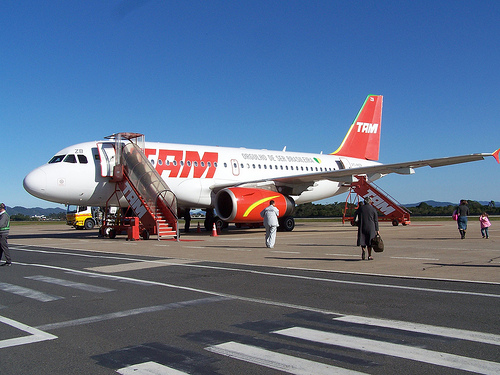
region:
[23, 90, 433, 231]
orange and white plane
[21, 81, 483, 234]
white and orange plane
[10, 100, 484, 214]
airplane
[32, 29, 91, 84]
white clouds in blue sky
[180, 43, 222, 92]
white clouds in blue sky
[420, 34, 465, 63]
white clouds in blue sky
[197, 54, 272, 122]
white clouds in blue sky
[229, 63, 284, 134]
white clouds in blue sky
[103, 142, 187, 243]
orange stairs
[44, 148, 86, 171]
plane cock pit windows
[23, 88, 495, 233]
white and red plane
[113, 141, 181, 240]
red stairs on plane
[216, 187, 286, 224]
red booster on plane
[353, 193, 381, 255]
man wearing black coat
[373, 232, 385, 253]
brown leather duffle bag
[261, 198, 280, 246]
man wearing white jacket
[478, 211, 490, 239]
person wearing pink jacket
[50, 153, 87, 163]
cockpit windows on plane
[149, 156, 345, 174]
windows on air plane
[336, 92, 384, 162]
red tail of plane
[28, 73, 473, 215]
orange and white airplane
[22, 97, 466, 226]
white and orange airplane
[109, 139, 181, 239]
airplane loading stairs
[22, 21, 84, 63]
white clouds in blue sky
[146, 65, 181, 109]
white clouds in blue sky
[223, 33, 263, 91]
white clouds in blue sky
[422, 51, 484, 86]
white clouds in blue sky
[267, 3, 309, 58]
white clouds in blue sky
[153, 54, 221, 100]
white clouds in blue sky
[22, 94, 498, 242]
Large passenger airplane parked on the tarmac.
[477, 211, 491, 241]
Little girl with pink coat and blue jeans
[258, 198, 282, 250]
Man wearing gray track suit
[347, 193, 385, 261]
Older woman with black over coat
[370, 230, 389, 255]
Woman holding brown bag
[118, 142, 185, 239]
Airplane stairs leading up airplane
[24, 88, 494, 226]
White airplane with red trim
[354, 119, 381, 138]
Airline name is TAM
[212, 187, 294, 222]
Propellor is red with yellow stripe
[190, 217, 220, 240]
Cones underneath airplane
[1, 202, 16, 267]
Airline worker walking away from plane